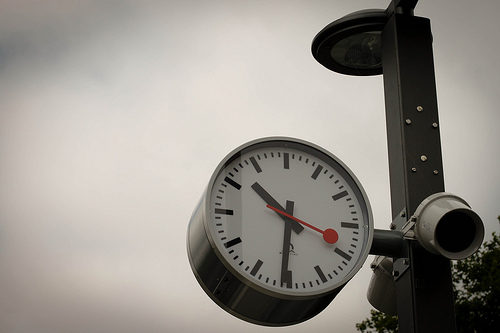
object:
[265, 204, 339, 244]
hand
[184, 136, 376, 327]
clock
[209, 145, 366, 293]
white face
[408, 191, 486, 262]
camera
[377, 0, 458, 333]
pole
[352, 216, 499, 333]
tree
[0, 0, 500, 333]
sky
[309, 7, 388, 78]
bulb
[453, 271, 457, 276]
leaves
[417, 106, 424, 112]
bolts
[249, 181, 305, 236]
hands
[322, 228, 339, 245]
circle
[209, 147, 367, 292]
10:30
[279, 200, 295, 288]
hand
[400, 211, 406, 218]
screws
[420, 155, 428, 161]
screws